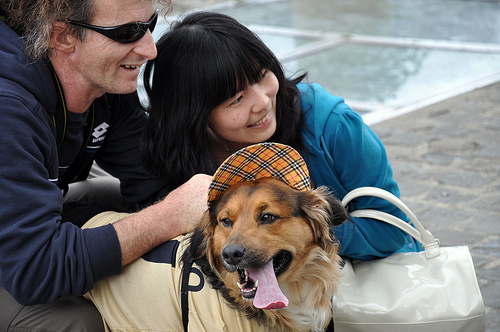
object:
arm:
[323, 104, 406, 259]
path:
[369, 93, 500, 294]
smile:
[242, 105, 275, 132]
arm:
[0, 91, 169, 307]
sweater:
[276, 79, 423, 258]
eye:
[226, 94, 244, 108]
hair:
[149, 8, 311, 178]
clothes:
[77, 239, 262, 332]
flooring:
[403, 96, 500, 250]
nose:
[248, 87, 270, 113]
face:
[70, 0, 160, 94]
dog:
[77, 177, 350, 330]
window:
[143, 0, 500, 132]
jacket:
[0, 36, 167, 303]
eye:
[258, 69, 268, 81]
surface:
[302, 40, 491, 108]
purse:
[318, 180, 491, 332]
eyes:
[258, 212, 283, 225]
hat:
[206, 143, 313, 223]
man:
[3, 0, 213, 332]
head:
[151, 12, 280, 144]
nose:
[222, 244, 247, 264]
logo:
[89, 121, 110, 143]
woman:
[147, 8, 427, 260]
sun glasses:
[60, 6, 160, 45]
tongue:
[246, 258, 290, 310]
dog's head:
[200, 182, 348, 303]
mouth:
[219, 259, 290, 299]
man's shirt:
[65, 109, 86, 130]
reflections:
[298, 45, 424, 95]